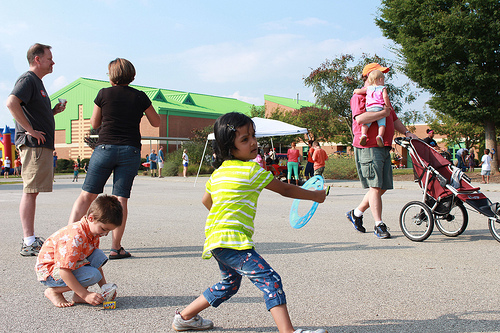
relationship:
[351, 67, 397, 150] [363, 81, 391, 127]
girl in pink and blue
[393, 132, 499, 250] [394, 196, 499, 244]
stroller with 3 wheels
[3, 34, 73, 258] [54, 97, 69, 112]
man holding cup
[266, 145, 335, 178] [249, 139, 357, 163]
people in background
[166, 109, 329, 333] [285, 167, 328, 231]
girl holding frisbee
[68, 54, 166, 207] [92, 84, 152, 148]
woman wearing black shirt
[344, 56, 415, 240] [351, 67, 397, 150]
man carrying child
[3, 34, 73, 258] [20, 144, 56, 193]
man wearing shorts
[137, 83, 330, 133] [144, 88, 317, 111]
building has green roof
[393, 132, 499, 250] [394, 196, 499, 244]
stroller with wheels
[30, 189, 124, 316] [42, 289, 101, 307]
boy with bare feet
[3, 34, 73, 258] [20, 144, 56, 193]
man wearing khaki shorts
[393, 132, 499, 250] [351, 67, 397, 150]
stroller for baby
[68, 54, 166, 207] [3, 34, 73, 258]
woman talking to man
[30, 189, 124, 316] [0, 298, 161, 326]
boy playing on ground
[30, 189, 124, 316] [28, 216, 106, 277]
boy wearing orange shirt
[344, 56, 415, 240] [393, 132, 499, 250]
man pushing stroller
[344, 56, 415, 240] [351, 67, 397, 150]
man carrying girl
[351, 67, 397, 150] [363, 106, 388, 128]
girl wearing blue pants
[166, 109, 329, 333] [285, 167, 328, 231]
girl about to throw frisbee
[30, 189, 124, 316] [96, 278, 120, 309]
boy with candy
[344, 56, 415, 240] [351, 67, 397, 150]
man holding baby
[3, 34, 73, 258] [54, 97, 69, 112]
man holding drink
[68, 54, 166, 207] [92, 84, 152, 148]
lady with back turne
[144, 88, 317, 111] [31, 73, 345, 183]
roof on building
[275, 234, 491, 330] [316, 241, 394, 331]
shadows on pavement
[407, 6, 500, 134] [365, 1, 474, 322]
trees on right side